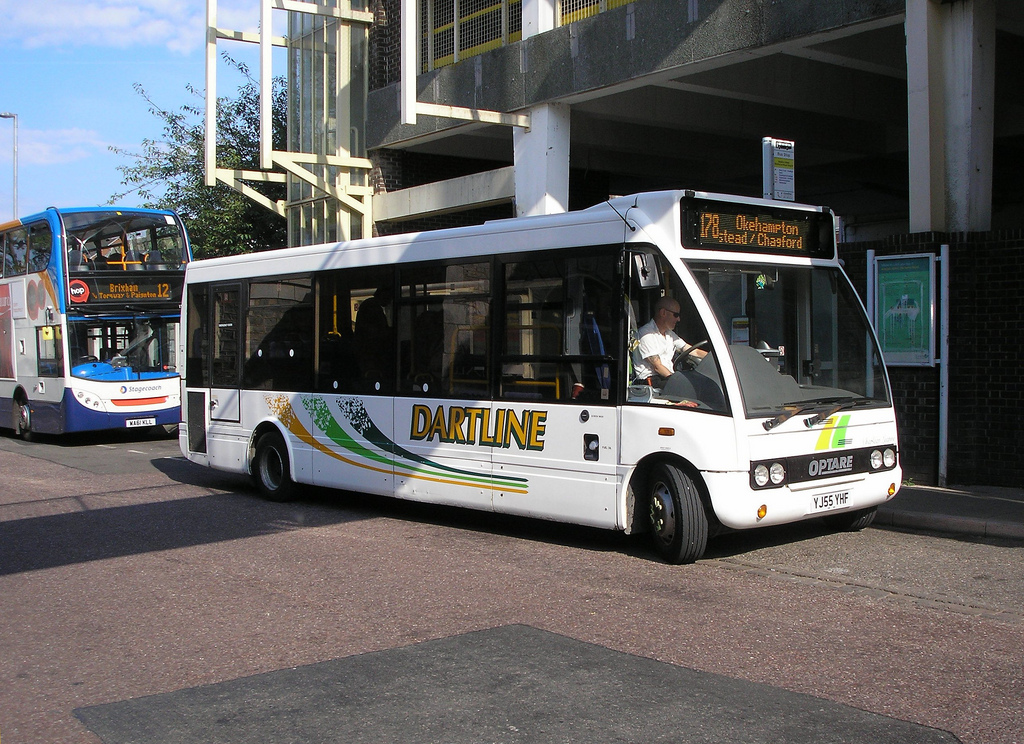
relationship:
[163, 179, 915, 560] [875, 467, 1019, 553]
bus by curb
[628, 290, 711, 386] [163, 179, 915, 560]
driver in bus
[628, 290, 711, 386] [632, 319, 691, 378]
driver wearing shirt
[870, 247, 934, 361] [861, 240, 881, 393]
sign on pole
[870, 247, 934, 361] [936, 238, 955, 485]
sign on pole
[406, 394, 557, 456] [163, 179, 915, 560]
dartline writing on bus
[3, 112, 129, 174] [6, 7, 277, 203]
clouds are in sky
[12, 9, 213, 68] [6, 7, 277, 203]
clouds are in sky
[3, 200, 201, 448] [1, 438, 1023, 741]
bus on street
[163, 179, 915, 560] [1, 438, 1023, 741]
bus on street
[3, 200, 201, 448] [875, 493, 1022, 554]
bus parked by curb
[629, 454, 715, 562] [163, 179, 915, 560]
tire on bus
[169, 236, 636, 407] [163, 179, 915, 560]
window on bus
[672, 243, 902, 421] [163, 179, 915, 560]
window on bus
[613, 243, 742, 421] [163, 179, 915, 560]
window on bus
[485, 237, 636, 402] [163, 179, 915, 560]
window on bus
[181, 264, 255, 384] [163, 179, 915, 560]
window on bus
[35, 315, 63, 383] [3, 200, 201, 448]
window on bus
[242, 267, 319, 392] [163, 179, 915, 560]
window on bus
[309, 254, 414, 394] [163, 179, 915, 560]
window on bus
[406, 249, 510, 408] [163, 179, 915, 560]
window on bus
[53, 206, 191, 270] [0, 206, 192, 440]
window on bus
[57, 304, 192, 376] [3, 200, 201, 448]
window on bus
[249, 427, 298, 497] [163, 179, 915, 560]
wheel on bus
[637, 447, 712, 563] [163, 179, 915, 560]
wheel on bus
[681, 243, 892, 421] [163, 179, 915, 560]
window on bus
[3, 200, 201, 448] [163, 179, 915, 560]
bus behind bus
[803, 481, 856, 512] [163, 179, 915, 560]
license plate on bus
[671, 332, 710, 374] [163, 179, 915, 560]
steering wheel on bus